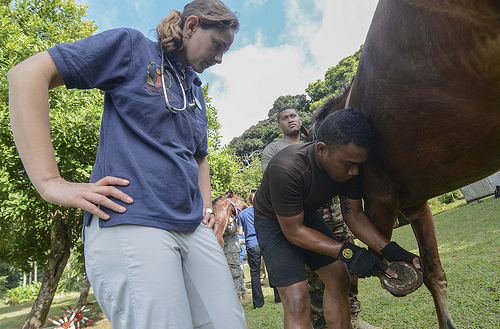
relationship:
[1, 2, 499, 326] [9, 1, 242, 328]
scene shows woman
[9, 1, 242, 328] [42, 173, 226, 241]
woman has hands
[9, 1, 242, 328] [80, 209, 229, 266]
woman has hips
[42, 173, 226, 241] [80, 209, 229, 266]
hands are on hips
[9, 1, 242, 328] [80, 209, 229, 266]
woman has hands on hips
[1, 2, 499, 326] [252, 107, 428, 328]
scene shows people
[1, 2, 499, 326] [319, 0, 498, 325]
scene shows horse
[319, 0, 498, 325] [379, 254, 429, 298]
horse has hoof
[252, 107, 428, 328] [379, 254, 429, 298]
people inspecting hoof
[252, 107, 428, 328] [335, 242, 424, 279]
people has hands of man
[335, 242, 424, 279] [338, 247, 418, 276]
hands of man have gloves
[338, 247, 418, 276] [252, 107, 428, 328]
gloves belong to people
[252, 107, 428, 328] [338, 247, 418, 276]
people wearing gloves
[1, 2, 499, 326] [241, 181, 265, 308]
scene shows trainer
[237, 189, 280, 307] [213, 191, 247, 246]
trainer in back with horse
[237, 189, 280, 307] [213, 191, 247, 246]
trainer with horse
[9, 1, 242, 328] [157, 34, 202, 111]
woman has stethoscope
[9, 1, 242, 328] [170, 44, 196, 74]
woman has neck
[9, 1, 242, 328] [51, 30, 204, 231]
woman wearing t-shirt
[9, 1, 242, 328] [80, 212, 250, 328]
woman has pants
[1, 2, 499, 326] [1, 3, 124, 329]
scene shows tree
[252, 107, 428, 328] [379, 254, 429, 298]
people looking at bottom of horse hoof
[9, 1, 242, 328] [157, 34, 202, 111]
woman wearing stethoscope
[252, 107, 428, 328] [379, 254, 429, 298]
people pointing at horse hoof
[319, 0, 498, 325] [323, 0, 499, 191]
horse has side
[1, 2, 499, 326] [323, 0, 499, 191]
scene shows side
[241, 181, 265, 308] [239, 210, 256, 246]
2nd woman has back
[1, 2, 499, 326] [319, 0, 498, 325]
scene shows part of horse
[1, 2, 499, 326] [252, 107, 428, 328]
scene features a people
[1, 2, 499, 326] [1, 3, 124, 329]
scene features a tree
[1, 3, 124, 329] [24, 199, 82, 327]
tree has trunk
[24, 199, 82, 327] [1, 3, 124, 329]
trunk belongs to tree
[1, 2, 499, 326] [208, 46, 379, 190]
scene shows tops of trees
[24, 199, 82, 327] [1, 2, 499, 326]
trunk of tree in scene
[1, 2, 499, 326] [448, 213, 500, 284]
scene features some grass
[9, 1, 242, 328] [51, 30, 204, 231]
woman wearing blue t-shirt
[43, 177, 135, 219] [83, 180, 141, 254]
woman's hand on hip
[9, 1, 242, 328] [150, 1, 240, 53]
woman has hair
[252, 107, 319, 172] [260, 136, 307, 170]
2nd man has grey t-shirt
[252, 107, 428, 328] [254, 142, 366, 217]
people wearing brown shirt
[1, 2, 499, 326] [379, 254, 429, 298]
scene shows bottom of horse hoof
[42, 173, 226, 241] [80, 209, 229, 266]
hands of woman  on hips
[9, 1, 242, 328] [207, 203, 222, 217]
woman wearing watch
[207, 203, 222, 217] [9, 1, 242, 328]
watch worn on left hand of woman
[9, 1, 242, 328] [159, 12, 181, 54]
woman has ponytail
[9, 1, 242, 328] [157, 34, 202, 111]
woman has stethoscope on neck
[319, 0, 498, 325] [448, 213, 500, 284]
horse standing upon grass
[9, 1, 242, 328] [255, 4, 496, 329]
doctor beside man and horse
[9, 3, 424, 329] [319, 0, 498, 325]
doctor and man standing beside of horse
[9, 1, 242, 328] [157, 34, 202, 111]
woman with stethoscope on neck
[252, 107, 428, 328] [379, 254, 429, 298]
people lifting up horses hoof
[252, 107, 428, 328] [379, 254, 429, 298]
people points at bottom of hoof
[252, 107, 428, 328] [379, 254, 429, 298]
people examines horse hoof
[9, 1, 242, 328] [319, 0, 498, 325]
woman standing by horse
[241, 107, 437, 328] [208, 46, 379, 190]
people on green grass by trees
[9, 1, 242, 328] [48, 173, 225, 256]
doctor looks down with hands on hips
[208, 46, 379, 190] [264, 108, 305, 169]
tree tops are behind 2nd man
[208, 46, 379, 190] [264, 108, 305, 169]
tree tops behind looking ahead 2nd man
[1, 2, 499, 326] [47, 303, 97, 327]
scene shows spiky objects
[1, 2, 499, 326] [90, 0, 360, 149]
scene shows sky